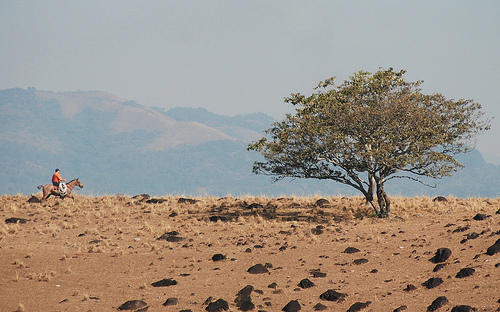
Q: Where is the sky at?
A: Above mountain.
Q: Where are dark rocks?
A: On ground.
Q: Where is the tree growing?
A: In ground.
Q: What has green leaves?
A: Large tree.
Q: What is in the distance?
A: Mountains.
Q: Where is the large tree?
A: In field.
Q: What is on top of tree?
A: Dry bushy top.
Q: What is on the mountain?
A: Dry hilly area.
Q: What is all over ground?
A: Medium to small rocks.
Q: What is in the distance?
A: A hill.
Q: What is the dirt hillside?
A: Brown.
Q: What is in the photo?
A: A tree.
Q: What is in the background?
A: A mountain.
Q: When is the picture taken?
A: Day time.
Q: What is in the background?
A: Hills.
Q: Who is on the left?
A: A rider.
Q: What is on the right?
A: A tree.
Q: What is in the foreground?
A: Dark rocks.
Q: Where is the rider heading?
A: Towards the tree.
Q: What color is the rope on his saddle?
A: White.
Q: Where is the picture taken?
A: In a very remote area of the mountains.